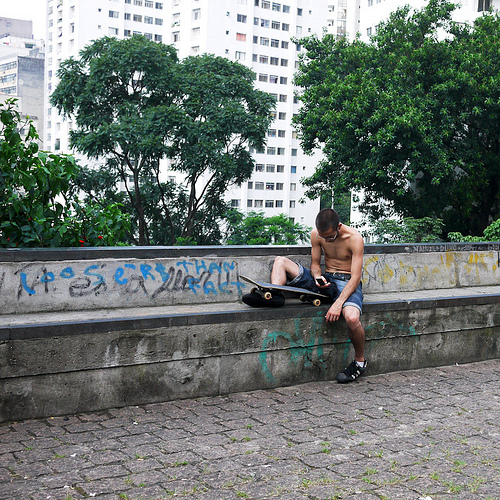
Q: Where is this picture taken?
A: In the City.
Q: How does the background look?
A: It shows a big building.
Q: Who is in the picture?
A: A Man.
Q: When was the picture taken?
A: In the daytime.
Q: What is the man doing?
A: Texting.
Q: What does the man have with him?
A: A Skateboard.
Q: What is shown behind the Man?
A: Trees.